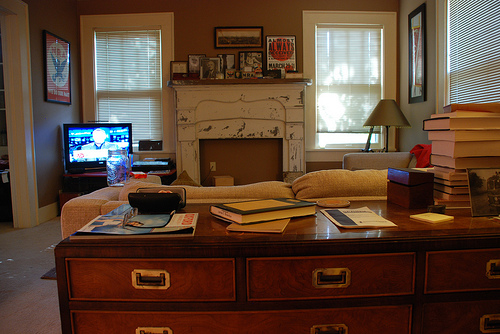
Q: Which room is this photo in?
A: It is at the living room.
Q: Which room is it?
A: It is a living room.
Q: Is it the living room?
A: Yes, it is the living room.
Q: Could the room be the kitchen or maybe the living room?
A: It is the living room.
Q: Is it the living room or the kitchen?
A: It is the living room.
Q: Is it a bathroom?
A: No, it is a living room.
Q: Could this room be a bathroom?
A: No, it is a living room.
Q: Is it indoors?
A: Yes, it is indoors.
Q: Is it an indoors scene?
A: Yes, it is indoors.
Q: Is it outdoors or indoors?
A: It is indoors.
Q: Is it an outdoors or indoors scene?
A: It is indoors.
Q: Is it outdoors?
A: No, it is indoors.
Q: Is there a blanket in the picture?
A: No, there are no blankets.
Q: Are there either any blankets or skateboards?
A: No, there are no blankets or skateboards.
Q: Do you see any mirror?
A: No, there are no mirrors.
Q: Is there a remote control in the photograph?
A: No, there are no remote controls.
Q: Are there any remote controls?
A: No, there are no remote controls.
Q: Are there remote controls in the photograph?
A: No, there are no remote controls.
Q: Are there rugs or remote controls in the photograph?
A: No, there are no remote controls or rugs.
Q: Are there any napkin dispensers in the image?
A: No, there are no napkin dispensers.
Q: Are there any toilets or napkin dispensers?
A: No, there are no napkin dispensers or toilets.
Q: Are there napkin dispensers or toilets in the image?
A: No, there are no napkin dispensers or toilets.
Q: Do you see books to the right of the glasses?
A: Yes, there is a book to the right of the glasses.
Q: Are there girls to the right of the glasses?
A: No, there is a book to the right of the glasses.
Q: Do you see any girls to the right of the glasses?
A: No, there is a book to the right of the glasses.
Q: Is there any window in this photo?
A: Yes, there is a window.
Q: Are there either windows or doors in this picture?
A: Yes, there is a window.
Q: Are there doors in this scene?
A: No, there are no doors.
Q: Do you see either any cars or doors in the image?
A: No, there are no doors or cars.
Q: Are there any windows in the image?
A: Yes, there is a window.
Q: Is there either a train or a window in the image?
A: Yes, there is a window.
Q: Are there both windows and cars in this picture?
A: No, there is a window but no cars.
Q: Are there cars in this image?
A: No, there are no cars.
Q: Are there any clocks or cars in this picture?
A: No, there are no cars or clocks.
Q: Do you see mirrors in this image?
A: No, there are no mirrors.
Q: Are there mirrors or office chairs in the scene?
A: No, there are no mirrors or office chairs.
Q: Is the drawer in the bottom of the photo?
A: Yes, the drawer is in the bottom of the image.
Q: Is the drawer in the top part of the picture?
A: No, the drawer is in the bottom of the image.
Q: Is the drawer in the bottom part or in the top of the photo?
A: The drawer is in the bottom of the image.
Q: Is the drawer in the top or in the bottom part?
A: The drawer is in the bottom of the image.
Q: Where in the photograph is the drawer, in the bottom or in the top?
A: The drawer is in the bottom of the image.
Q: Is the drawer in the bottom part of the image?
A: Yes, the drawer is in the bottom of the image.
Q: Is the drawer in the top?
A: No, the drawer is in the bottom of the image.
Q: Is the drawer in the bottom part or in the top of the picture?
A: The drawer is in the bottom of the image.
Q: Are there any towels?
A: No, there are no towels.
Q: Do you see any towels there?
A: No, there are no towels.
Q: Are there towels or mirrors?
A: No, there are no towels or mirrors.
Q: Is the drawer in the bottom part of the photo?
A: Yes, the drawer is in the bottom of the image.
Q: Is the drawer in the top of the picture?
A: No, the drawer is in the bottom of the image.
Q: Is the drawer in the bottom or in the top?
A: The drawer is in the bottom of the image.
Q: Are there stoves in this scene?
A: No, there are no stoves.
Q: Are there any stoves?
A: No, there are no stoves.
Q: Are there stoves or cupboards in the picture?
A: No, there are no stoves or cupboards.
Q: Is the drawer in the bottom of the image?
A: Yes, the drawer is in the bottom of the image.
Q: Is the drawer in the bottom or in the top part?
A: The drawer is in the bottom of the image.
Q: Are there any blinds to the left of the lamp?
A: Yes, there are blinds to the left of the lamp.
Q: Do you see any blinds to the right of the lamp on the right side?
A: No, the blinds are to the left of the lamp.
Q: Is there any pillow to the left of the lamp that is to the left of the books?
A: No, there are blinds to the left of the lamp.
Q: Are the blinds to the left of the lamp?
A: Yes, the blinds are to the left of the lamp.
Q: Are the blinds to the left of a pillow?
A: No, the blinds are to the left of the lamp.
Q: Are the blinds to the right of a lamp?
A: No, the blinds are to the left of a lamp.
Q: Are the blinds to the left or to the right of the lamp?
A: The blinds are to the left of the lamp.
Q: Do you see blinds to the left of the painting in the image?
A: Yes, there are blinds to the left of the painting.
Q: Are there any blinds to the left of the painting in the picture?
A: Yes, there are blinds to the left of the painting.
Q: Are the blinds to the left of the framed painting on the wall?
A: Yes, the blinds are to the left of the painting.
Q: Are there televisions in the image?
A: Yes, there is a television.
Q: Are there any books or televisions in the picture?
A: Yes, there is a television.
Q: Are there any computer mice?
A: No, there are no computer mice.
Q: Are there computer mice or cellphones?
A: No, there are no computer mice or cellphones.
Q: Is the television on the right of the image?
A: No, the television is on the left of the image.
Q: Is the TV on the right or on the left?
A: The TV is on the left of the image.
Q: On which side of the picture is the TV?
A: The TV is on the left of the image.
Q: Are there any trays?
A: No, there are no trays.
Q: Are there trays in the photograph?
A: No, there are no trays.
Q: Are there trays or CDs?
A: No, there are no trays or cds.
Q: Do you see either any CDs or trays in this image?
A: No, there are no trays or cds.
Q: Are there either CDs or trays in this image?
A: No, there are no trays or cds.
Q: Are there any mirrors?
A: No, there are no mirrors.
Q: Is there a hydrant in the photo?
A: No, there are no fire hydrants.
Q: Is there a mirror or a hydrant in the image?
A: No, there are no fire hydrants or mirrors.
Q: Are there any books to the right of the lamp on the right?
A: Yes, there are books to the right of the lamp.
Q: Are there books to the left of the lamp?
A: No, the books are to the right of the lamp.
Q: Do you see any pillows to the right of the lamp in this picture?
A: No, there are books to the right of the lamp.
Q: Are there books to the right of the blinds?
A: Yes, there are books to the right of the blinds.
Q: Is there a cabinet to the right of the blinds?
A: No, there are books to the right of the blinds.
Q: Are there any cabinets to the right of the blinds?
A: No, there are books to the right of the blinds.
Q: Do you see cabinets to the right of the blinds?
A: No, there are books to the right of the blinds.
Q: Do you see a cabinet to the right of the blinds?
A: No, there are books to the right of the blinds.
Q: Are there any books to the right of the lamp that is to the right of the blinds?
A: Yes, there are books to the right of the lamp.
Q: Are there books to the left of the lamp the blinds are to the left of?
A: No, the books are to the right of the lamp.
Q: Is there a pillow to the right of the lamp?
A: No, there are books to the right of the lamp.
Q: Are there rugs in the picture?
A: No, there are no rugs.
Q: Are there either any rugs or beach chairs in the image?
A: No, there are no rugs or beach chairs.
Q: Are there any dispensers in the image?
A: No, there are no dispensers.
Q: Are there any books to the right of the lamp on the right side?
A: Yes, there are books to the right of the lamp.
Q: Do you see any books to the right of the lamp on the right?
A: Yes, there are books to the right of the lamp.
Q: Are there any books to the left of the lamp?
A: No, the books are to the right of the lamp.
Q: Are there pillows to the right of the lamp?
A: No, there are books to the right of the lamp.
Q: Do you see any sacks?
A: No, there are no sacks.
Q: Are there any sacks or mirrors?
A: No, there are no sacks or mirrors.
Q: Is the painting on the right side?
A: Yes, the painting is on the right of the image.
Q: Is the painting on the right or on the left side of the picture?
A: The painting is on the right of the image.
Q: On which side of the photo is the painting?
A: The painting is on the right of the image.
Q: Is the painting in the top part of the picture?
A: Yes, the painting is in the top of the image.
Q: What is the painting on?
A: The painting is on the wall.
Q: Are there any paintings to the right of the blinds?
A: Yes, there is a painting to the right of the blinds.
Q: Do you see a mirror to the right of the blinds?
A: No, there is a painting to the right of the blinds.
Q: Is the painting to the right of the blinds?
A: Yes, the painting is to the right of the blinds.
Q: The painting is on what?
A: The painting is on the wall.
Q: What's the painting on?
A: The painting is on the wall.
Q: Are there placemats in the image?
A: No, there are no placemats.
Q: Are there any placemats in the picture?
A: No, there are no placemats.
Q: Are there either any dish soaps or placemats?
A: No, there are no placemats or dish soaps.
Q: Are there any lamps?
A: Yes, there is a lamp.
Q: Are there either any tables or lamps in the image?
A: Yes, there is a lamp.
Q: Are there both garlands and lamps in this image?
A: No, there is a lamp but no garlands.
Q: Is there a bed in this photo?
A: No, there are no beds.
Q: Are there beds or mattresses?
A: No, there are no beds or mattresses.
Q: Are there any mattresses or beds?
A: No, there are no beds or mattresses.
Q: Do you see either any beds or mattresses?
A: No, there are no beds or mattresses.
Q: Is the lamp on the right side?
A: Yes, the lamp is on the right of the image.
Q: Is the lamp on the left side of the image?
A: No, the lamp is on the right of the image.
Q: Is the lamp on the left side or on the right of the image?
A: The lamp is on the right of the image.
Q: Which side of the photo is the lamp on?
A: The lamp is on the right of the image.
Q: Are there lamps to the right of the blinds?
A: Yes, there is a lamp to the right of the blinds.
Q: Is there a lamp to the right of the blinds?
A: Yes, there is a lamp to the right of the blinds.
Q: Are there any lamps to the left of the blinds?
A: No, the lamp is to the right of the blinds.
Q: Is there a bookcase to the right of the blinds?
A: No, there is a lamp to the right of the blinds.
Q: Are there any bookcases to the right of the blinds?
A: No, there is a lamp to the right of the blinds.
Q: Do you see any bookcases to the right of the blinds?
A: No, there is a lamp to the right of the blinds.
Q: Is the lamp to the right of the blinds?
A: Yes, the lamp is to the right of the blinds.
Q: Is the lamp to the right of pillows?
A: No, the lamp is to the right of the blinds.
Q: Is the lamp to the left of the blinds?
A: No, the lamp is to the right of the blinds.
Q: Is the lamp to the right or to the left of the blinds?
A: The lamp is to the right of the blinds.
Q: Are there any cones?
A: No, there are no cones.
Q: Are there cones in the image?
A: No, there are no cones.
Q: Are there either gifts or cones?
A: No, there are no cones or gifts.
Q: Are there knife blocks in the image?
A: No, there are no knife blocks.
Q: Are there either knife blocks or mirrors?
A: No, there are no knife blocks or mirrors.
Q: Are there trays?
A: No, there are no trays.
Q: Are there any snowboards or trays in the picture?
A: No, there are no trays or snowboards.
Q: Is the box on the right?
A: Yes, the box is on the right of the image.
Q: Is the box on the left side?
A: No, the box is on the right of the image.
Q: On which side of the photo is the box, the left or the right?
A: The box is on the right of the image.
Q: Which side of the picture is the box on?
A: The box is on the right of the image.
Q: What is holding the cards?
A: The box is holding the cards.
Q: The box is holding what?
A: The box is holding the cards.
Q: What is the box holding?
A: The box is holding the cards.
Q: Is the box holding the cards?
A: Yes, the box is holding the cards.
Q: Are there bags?
A: No, there are no bags.